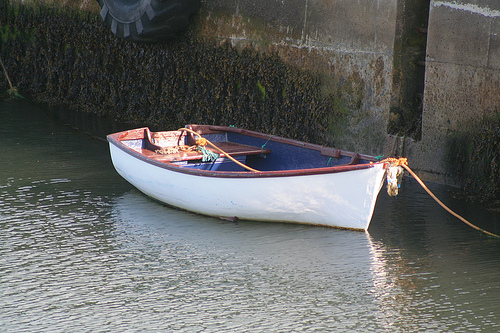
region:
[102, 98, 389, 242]
the boat is on the water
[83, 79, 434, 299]
one boat on the water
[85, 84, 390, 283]
the boat is white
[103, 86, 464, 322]
the boat is made of wood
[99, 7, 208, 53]
the tire is black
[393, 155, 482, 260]
the rope is orange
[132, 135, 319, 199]
the seat is brown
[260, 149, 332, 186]
inside of the boat is purple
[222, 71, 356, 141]
seaweeds on the wall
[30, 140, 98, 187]
the water is green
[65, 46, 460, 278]
There is a boat in the water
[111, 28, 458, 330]
There is only one boat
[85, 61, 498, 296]
The boat is tied up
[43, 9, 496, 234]
There is a wall behind the boat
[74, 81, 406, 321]
The boat is white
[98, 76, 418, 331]
There is a white boat in the water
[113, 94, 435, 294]
The interior of the boat is blue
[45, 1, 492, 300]
There is a wall behind the white boat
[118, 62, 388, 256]
The seat in the boat is brown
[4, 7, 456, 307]
The photo was taken during the day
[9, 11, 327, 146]
Moss growing on the side of a wall.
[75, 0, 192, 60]
A tire hanging off the side of the wall.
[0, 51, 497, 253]
A piece of rope that is going across the boat.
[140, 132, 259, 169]
An empty bench in the back of a boat.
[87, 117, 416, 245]
A white boat in the water.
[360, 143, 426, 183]
A knot in the middle of the rope.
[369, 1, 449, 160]
A drain in the side of a wall.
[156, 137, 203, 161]
A piece of rope in the back of the boat.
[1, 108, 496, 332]
A body of water.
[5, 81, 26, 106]
Moss growing on the rope.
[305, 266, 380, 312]
part of some water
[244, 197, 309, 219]
side of a boat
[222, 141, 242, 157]
bench of a boat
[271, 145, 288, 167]
inner part of the boat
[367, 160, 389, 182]
tip of the boat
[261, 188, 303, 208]
white colour on the boat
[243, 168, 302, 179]
wooden edge of the boat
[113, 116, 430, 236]
a rowboat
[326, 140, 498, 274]
the bow of the boat is tied up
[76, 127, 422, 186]
the boat is wooden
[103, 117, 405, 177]
the trim around the boat is brownish red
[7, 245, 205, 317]
the water is green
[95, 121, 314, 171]
there appears to be only one seat in the boat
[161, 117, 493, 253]
the rope holding the boat is yellow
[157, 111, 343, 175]
the inside of the boat is blue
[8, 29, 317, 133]
the wall looks like it has barnacles growing on it